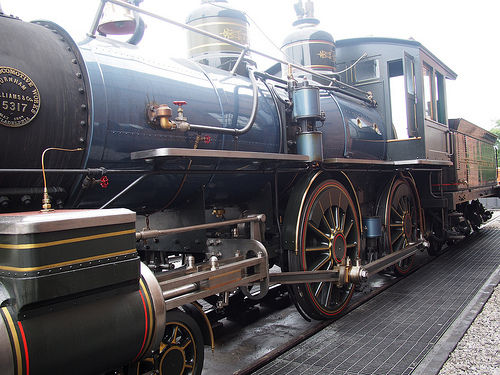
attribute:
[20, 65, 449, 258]
train — part, blue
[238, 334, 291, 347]
floor — part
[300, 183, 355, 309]
wheel — part, edge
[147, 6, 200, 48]
metal — part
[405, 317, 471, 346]
ground — part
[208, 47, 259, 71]
engine — board, vintage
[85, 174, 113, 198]
handle — red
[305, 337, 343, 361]
gravel — gray